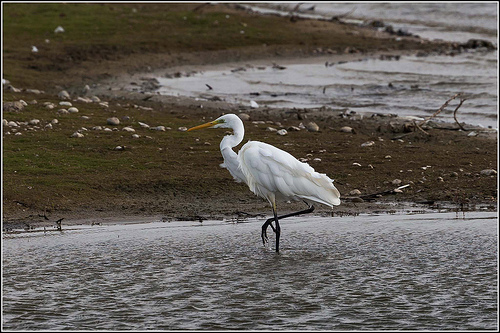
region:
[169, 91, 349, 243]
white bird standing in water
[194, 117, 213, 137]
yellow bill of white bird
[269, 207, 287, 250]
brown leg of white bird standing in water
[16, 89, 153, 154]
brown and tan rocks near water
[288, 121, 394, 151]
brown and tan rocks near water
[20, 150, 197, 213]
green and brown grass near water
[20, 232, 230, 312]
brown water near beach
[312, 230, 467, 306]
brown water near beach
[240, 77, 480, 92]
brown water near beach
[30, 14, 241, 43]
green and brown grass near water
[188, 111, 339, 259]
white heron in water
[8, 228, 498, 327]
ice in lake water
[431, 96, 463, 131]
brown branch in mud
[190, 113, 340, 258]
heron standing on one leg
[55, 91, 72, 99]
grey rock on grass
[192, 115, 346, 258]
white bird standing in lake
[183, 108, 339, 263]
white bird with orange beak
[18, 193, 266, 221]
mud next to lake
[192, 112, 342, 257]
white bird with black legs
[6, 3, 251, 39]
patch of green grass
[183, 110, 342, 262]
the heron is white with a yellow beak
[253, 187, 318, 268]
the heron has one leg bent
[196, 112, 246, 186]
the heron has a long neck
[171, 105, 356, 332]
the bird is wading in the water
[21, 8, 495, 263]
the shore has rocks strewn about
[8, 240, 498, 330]
the water has ripples and is dark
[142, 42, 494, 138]
the water is flowing towards shore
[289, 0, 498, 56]
the water has small waves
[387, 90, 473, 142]
branches are on the shore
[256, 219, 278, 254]
the heron has clawed feet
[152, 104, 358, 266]
bird standing in water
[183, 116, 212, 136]
bird with yellow beak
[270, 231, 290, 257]
bird with black leg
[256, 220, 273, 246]
black leg pulled up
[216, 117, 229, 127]
eye on side of bird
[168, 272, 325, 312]
ocean with waves in water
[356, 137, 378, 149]
rock in grassy area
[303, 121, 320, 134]
rock in grassy area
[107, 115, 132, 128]
rock in grassy area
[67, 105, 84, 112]
rock in grassy area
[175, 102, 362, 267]
Stork standing on one leg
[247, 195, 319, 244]
Stork has black leg lifted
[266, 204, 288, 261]
Stork has straight black leg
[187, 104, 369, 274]
Stork standing in water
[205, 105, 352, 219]
Stork has white feathers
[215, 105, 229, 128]
Stork has a dark eye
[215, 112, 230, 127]
Stork's eye is open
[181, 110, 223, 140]
Stork has yellow beak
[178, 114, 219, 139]
Stork's beak is long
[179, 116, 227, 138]
Stork's beak is pointed